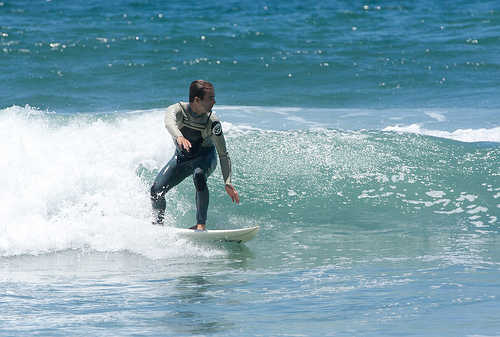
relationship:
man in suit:
[146, 78, 243, 232] [169, 115, 231, 193]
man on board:
[146, 78, 243, 232] [225, 215, 261, 248]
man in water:
[146, 78, 243, 232] [289, 44, 419, 212]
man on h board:
[146, 78, 243, 232] [225, 215, 261, 248]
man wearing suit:
[146, 78, 243, 232] [169, 115, 231, 193]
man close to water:
[146, 78, 243, 232] [289, 44, 419, 212]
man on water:
[146, 78, 243, 232] [289, 44, 419, 212]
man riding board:
[146, 78, 243, 232] [225, 215, 261, 248]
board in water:
[225, 215, 261, 248] [289, 44, 419, 212]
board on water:
[225, 215, 261, 248] [289, 44, 419, 212]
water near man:
[289, 44, 419, 212] [146, 78, 243, 232]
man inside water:
[146, 78, 243, 232] [289, 44, 419, 212]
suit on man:
[169, 115, 231, 193] [146, 78, 243, 232]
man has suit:
[146, 78, 243, 232] [169, 115, 231, 193]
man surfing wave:
[144, 75, 246, 228] [22, 104, 483, 236]